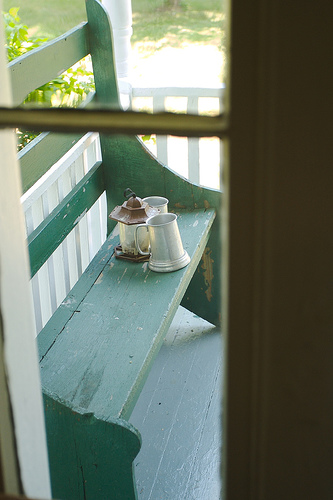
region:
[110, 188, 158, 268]
the lantern on the bench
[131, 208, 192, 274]
the mug on the bench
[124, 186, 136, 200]
the hook on the lantern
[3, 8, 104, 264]
the back of the bench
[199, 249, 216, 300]
the paint peeling off the leg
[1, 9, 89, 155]
the bushes behind the deck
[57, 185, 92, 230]
the paint peeling from the back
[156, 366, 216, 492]
the wooden floor of the deck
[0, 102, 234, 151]
the trim on the window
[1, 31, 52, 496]
the white drape on the window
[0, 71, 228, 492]
this is a bench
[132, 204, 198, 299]
this is a cup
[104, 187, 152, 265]
this is a kettle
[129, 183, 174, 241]
this is a cup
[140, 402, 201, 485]
this is made of wood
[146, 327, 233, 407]
this is made of wood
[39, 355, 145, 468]
this is made of wood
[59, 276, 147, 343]
this is made of wood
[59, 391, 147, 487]
this is made of wood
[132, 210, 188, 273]
a silver cup on a bench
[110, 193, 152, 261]
a bird feeder on a bench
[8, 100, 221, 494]
a green wooden bench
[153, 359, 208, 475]
a gray wooden floor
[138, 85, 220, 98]
a pouch railing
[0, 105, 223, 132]
a wooden window panel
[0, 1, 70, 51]
a leafy green bush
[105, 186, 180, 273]
stuff on a green bench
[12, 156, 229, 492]
a green bench on pouch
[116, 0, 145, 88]
a porch wooden post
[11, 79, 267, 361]
white railing along the deck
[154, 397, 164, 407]
speck on the deck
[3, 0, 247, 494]
bench on the deck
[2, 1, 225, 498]
bench is painted green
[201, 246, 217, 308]
paint peeling off the wood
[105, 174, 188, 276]
objects sitting on the bench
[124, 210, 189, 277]
silver mug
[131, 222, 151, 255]
handle on the silver mug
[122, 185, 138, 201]
black hook on top of the object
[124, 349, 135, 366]
small specks on the bench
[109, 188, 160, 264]
a small bird feeder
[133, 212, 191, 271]
a metal drinking mug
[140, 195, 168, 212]
a metal drinking mug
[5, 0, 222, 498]
an outdoor wooden bench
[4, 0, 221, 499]
a weather worn green bench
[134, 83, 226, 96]
a white wood bannister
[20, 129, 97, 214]
a white wood bannister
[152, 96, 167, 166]
a white wood rail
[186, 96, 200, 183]
a white wood rail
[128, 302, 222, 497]
blue painted wood decking